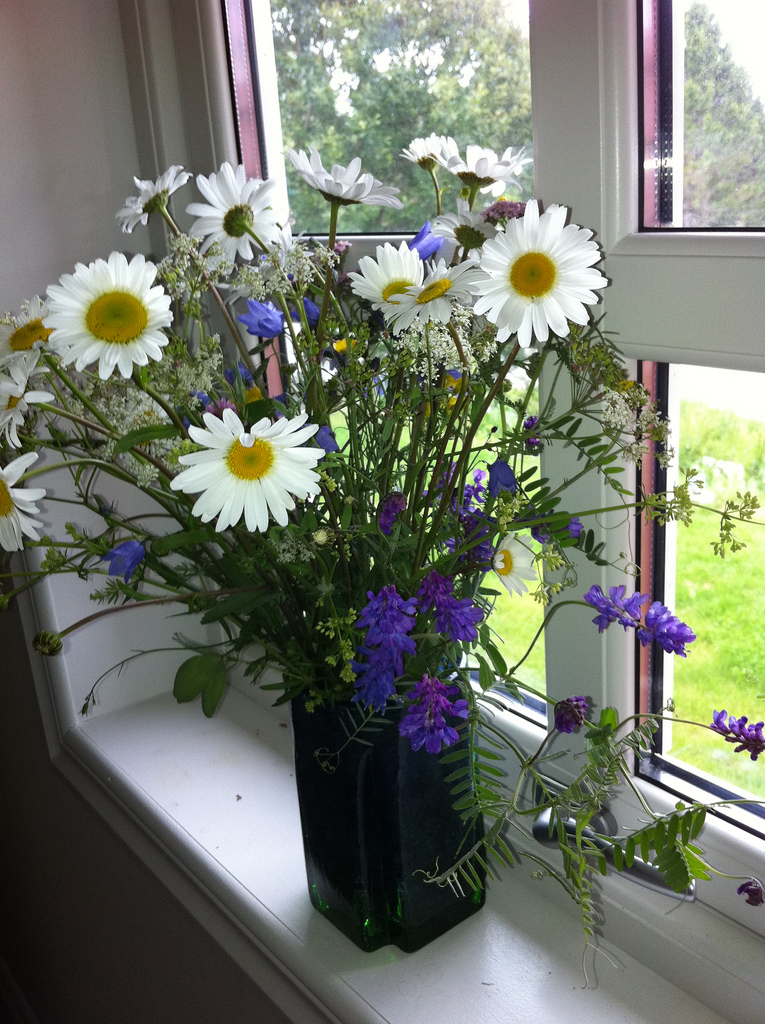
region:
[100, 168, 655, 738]
white and purple flowers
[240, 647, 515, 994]
black vase under flowers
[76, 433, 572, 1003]
flowers on white ledge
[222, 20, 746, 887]
white frame around window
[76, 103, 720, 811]
green leaves on flowers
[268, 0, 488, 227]
green trees outside window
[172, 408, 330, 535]
Small white flower in flower vase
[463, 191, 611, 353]
Small white flower in flower vase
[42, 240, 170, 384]
Small white flower in flower vase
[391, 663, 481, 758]
Small purple flower in flower vase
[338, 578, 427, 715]
Small purple flower in flower vase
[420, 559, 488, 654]
Small purple flower in flower vase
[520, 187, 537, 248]
White petal on the flower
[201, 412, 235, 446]
White petal on the flower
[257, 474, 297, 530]
White petal on the flower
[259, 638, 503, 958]
green vase holding the flowers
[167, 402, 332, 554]
daisy that is lowest and facing us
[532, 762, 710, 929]
silver handle of the window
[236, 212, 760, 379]
horizontal cross of the window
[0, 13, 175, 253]
white part of the wall next to the window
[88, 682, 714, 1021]
bottom ledge of the window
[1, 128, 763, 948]
the flowers and the vase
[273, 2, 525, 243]
tree in the back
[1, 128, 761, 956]
Flowers on the green glass vase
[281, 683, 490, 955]
Green glass vase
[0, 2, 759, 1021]
Flower vase in the window sill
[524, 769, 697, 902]
Handle knob of the window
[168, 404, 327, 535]
White and yellow flower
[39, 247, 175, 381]
White and yellow flower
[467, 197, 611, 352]
White and yellow flower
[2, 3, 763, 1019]
Flowers vase by the window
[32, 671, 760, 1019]
White window sill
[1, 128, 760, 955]
Beautiful flowers in the vase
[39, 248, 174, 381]
Flower has white petals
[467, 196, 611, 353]
Flower has white petals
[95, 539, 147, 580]
Purple flower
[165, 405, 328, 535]
Yellow and white flower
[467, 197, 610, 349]
Yellow and white flower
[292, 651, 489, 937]
A black flower vase.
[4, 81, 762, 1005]
Flowers in the windowsill.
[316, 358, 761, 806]
A patch of green grass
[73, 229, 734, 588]
White babys breath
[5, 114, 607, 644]
White and yellow flowers in a vase.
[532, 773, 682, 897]
A silver latch on a window.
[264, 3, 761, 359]
Green leafy trees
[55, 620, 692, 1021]
A white windowsill.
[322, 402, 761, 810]
Purple flowers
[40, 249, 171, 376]
flower attached to green stem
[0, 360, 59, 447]
flower attached to green stem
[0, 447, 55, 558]
flower attached to green stem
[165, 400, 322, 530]
flower attached to green stem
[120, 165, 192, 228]
flower attached to green stem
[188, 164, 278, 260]
flower attached to green stem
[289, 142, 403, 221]
flower attached to green stem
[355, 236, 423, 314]
flower attached to green stem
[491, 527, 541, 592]
flower attached to green stem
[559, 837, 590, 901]
leaves on the plant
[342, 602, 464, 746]
flowers on the plant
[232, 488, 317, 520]
the flower is white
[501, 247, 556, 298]
the flower is yellow